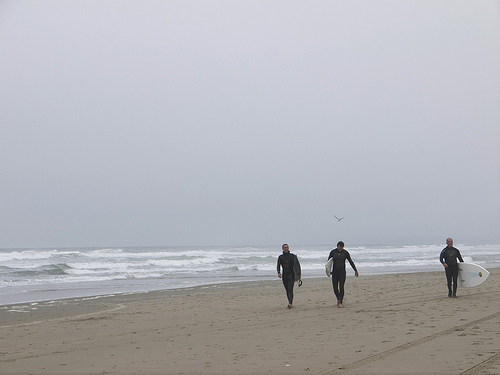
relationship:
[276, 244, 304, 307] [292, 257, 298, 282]
man with surfboard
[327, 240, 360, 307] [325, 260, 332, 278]
man with surfboard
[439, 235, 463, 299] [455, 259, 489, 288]
man with surfboard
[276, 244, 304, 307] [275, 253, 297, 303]
man wearing wet suit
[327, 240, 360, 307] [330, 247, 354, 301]
man wearing wet suit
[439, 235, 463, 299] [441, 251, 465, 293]
man wearing wet suit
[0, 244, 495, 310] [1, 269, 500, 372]
water crashing into beach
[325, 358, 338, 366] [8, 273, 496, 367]
footprint in sand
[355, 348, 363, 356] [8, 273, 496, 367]
footprint in sand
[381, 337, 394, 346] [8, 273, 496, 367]
footprint in sand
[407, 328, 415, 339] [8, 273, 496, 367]
footprint in sand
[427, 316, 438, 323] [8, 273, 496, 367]
footprint in sand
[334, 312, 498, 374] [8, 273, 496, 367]
track in sand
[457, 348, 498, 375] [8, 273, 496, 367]
track in sand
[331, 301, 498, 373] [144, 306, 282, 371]
tire tracks in sand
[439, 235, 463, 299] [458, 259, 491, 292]
man carry surfboard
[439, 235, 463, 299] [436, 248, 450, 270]
man has arm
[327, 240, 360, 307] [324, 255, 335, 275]
man carry surfboard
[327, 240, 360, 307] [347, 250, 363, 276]
man has arm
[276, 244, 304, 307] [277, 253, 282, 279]
man has arm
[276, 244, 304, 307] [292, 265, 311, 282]
man holding surfboard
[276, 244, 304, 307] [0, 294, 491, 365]
man walking on beach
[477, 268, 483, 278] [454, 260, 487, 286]
logo on surfboard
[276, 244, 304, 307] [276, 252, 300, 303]
man wearing wetsuits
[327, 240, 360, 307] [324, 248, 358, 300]
man wearing wetsuits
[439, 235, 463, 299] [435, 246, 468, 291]
man wearing wetsuits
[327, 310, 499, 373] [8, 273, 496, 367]
tracks in sand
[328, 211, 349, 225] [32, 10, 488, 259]
bird flying in sky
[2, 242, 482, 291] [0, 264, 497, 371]
waves coming to shore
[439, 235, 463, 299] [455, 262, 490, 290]
man holding surfboard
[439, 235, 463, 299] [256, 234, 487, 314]
man wearing surfwear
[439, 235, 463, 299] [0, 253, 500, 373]
man walking along beach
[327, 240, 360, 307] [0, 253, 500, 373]
man walking along beach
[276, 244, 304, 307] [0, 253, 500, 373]
man walking along beach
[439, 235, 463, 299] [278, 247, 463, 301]
man are wearing wetsuits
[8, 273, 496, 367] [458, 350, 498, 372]
sand has track mark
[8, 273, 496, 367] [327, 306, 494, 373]
sand has track mark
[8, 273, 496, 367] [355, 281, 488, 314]
sand has track mark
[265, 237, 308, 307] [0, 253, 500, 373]
man walking along a beach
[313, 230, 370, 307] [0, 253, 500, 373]
man walking along a beach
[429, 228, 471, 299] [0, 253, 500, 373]
man walking along a beach